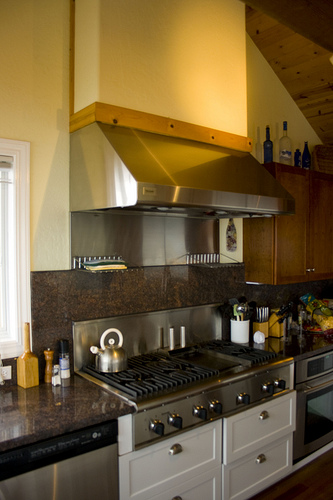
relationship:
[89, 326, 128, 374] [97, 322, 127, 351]
kettle has handle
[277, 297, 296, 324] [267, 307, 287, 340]
knieves are on nlock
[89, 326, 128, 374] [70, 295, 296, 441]
kettle on cooktop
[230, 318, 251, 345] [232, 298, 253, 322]
bucket containing utensils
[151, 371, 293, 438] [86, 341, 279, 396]
control knobs for stove top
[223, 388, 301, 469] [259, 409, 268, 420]
drawer with handle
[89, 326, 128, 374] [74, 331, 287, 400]
kettle on stove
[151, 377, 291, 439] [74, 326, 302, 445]
control knobs on stove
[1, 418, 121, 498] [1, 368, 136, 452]
dishwasher under countertop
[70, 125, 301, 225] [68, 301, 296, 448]
fan over stove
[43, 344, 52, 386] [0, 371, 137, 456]
grinder on counter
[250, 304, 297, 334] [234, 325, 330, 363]
knife block on counter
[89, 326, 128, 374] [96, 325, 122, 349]
kettle with handle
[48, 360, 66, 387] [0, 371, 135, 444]
salt shaker on counter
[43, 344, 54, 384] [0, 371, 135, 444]
grinder on counter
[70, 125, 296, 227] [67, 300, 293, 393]
fan over stove top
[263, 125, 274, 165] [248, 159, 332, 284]
bottle on top of cabinet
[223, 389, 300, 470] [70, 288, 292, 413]
drawers under stove top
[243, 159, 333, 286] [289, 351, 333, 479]
cabinet above oven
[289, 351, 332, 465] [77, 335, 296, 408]
oven to right of stove top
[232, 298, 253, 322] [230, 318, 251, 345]
utensils in bucket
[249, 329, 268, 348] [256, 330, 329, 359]
timer on counter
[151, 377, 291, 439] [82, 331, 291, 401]
control knobs for stove top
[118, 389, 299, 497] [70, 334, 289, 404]
drawers under stove top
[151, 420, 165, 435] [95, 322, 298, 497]
knob on stove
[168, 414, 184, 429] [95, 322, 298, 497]
knob on stove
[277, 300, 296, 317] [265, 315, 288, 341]
knieves in holder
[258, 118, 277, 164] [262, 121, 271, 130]
bottle has cork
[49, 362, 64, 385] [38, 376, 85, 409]
salt on counter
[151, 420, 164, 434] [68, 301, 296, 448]
knob on stove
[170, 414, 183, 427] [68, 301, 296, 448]
knob on stove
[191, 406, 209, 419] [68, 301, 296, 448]
knob on stove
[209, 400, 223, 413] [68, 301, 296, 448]
knob on stove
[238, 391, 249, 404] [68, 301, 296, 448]
knob on stove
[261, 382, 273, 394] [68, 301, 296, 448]
knob on stove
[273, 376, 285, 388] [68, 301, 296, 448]
knob on stove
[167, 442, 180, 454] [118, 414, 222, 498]
handle on drawer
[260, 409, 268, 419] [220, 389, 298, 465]
handle on drawer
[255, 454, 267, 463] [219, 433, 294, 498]
handle on drawer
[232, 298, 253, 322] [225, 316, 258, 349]
utensils are inside bucket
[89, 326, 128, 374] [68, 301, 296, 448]
kettle on stove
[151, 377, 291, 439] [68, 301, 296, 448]
control knobs are on stove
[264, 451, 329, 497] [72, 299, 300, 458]
ground in front of stove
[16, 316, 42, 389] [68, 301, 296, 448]
object next to stove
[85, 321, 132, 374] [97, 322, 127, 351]
kettle has handle